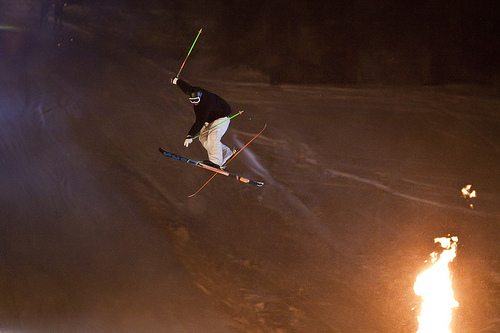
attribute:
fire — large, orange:
[410, 230, 465, 331]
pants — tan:
[197, 112, 242, 169]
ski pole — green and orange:
[218, 120, 226, 127]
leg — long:
[204, 118, 230, 165]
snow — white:
[13, 17, 490, 327]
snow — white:
[62, 121, 199, 283]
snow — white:
[0, 0, 498, 331]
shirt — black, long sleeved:
[176, 77, 233, 129]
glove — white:
[171, 78, 176, 83]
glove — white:
[183, 137, 192, 145]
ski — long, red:
[157, 145, 262, 188]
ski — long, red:
[185, 126, 272, 196]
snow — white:
[25, 126, 186, 309]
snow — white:
[26, 83, 165, 315]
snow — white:
[37, 96, 161, 309]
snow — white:
[126, 198, 376, 301]